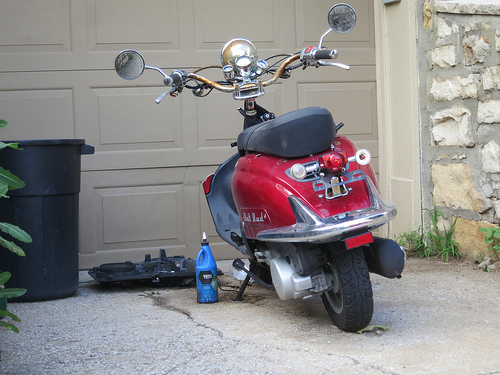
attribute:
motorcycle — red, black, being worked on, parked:
[114, 2, 407, 332]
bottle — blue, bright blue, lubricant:
[196, 231, 219, 303]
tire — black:
[320, 241, 373, 332]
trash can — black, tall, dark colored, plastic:
[2, 139, 94, 301]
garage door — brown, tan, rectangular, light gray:
[1, 1, 378, 271]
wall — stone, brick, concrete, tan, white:
[416, 2, 500, 271]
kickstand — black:
[233, 270, 253, 301]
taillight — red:
[318, 149, 347, 173]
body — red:
[203, 137, 380, 242]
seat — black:
[237, 108, 337, 157]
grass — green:
[400, 207, 460, 262]